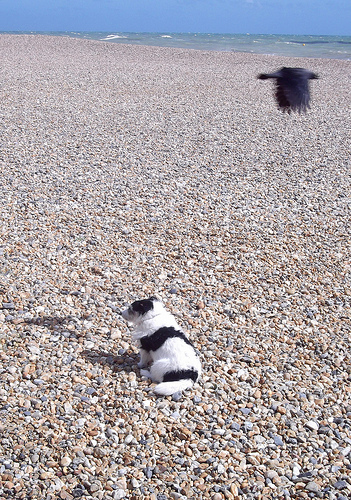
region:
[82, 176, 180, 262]
a bunch of rocks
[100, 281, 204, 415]
a dog laying in the rocks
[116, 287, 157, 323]
the head of a black and white dog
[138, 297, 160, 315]
the ear of a black and white dog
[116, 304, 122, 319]
the nose of a black and white dog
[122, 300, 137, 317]
the eye of a black and white dog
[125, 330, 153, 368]
the arm of a black and white dog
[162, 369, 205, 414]
the tail of a black and white dog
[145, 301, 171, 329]
the coat of a black and white dog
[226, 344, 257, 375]
part of a ground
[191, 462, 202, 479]
part of a stone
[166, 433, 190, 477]
part of a ground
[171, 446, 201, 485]
part of a gropunmd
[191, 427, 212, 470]
part of a floor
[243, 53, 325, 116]
the bird flying in the air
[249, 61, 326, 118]
the black bird flapping it's wings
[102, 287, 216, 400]
the black and white dog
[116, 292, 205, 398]
the dog on the rocks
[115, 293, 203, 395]
the balck and white laying on the rocks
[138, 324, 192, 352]
the black stripe on the dogs back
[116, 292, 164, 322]
the hea dof the dog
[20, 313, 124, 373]
the shadows on the rocks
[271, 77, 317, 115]
the balck wings of the bird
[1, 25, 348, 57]
the waves in the ocean water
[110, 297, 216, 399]
dog sitting down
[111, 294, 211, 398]
the dog is black and white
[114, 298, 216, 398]
the dog is on the beach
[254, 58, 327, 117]
the crow is black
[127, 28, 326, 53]
the sea is in th background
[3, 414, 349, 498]
the ground is covered with pebbles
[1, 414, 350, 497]
the pebbles are brown and grey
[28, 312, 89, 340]
shadow is on the ground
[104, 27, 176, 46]
ripples are in the sea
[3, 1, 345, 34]
the sky has no clouds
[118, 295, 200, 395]
the dog is sitting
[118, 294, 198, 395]
the animal on the rocks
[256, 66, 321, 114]
the bird in motion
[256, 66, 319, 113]
the bird in mid air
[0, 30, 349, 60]
the body of water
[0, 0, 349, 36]
the sky above the water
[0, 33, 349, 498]
the rocks on the ground